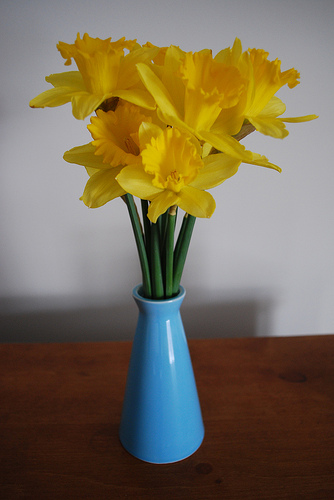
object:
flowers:
[114, 119, 245, 225]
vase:
[117, 283, 206, 467]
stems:
[165, 209, 177, 299]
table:
[0, 332, 333, 500]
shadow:
[0, 295, 274, 347]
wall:
[0, 0, 332, 344]